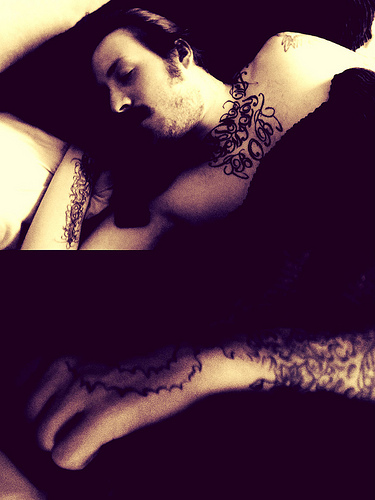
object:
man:
[17, 5, 375, 249]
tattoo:
[200, 63, 285, 180]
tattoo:
[61, 328, 211, 403]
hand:
[23, 323, 270, 471]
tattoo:
[59, 147, 98, 251]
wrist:
[68, 132, 103, 155]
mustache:
[117, 105, 156, 123]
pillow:
[0, 0, 122, 153]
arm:
[19, 140, 106, 251]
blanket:
[152, 70, 373, 245]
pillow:
[0, 115, 114, 253]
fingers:
[51, 412, 104, 473]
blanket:
[111, 405, 374, 494]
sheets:
[0, 105, 113, 253]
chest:
[192, 71, 326, 227]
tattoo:
[213, 321, 374, 398]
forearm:
[218, 307, 367, 402]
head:
[79, 8, 207, 143]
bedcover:
[0, 220, 374, 499]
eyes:
[117, 64, 137, 89]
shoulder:
[247, 31, 325, 74]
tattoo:
[277, 32, 298, 54]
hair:
[120, 4, 200, 66]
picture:
[1, 6, 374, 498]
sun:
[288, 36, 349, 79]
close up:
[0, 248, 373, 500]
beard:
[149, 89, 205, 140]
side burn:
[158, 62, 185, 82]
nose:
[110, 89, 130, 114]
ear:
[172, 37, 193, 71]